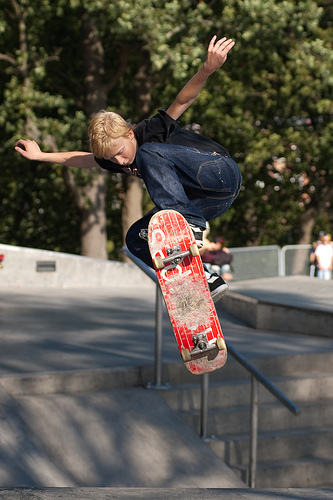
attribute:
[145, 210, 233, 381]
skateboard — scratched up, red, white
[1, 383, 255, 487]
ramp — grey, concrete, partially shaded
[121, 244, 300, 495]
rail — metal, gray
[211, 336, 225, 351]
wheels — white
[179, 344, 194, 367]
wheels — whit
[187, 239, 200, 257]
wheels — whi, white, light colored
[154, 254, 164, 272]
wheels — white, light colored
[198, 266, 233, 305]
shoe — black, white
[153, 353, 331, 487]
steps — grey, concrete, cement, gray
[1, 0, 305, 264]
trees — large, background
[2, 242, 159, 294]
wall — concrete, gray, cement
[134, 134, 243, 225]
jeans — blue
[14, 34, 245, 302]
boy — in air, jumping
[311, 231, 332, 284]
person — wearing white, background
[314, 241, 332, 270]
shirt — white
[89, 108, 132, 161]
hair — blonde, short, blond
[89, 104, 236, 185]
t-shirt — black